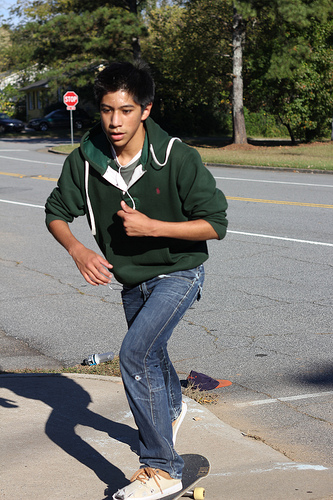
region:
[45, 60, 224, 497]
boy on skateboard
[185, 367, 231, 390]
blue and orange baseball cap on ground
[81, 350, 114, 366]
empty plastic bottle in the street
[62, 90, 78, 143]
stop sign in distance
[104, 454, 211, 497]
skateboard with white wheels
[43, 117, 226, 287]
green hoodie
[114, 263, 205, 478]
blue jeans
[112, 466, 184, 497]
tan shoe with a hole in the toe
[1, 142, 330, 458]
street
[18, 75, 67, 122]
house in background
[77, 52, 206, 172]
He is not an adult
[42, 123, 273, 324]
His jacket is dark green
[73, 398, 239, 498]
The skateboard is black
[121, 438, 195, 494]
His laces are orange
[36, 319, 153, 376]
Trash on the ground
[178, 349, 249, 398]
Someone's hat is not on their head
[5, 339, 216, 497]
A shadow is on the sidewalk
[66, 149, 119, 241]
The laces are white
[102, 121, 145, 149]
His mouth is open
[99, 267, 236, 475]
His jeans are dark blue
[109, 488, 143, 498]
hole in left sneaker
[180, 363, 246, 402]
orange and blue baseball hat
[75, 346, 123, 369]
empty plastic drink bottle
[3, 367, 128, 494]
black shadow of skateboarder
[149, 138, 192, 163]
White string on skateboarder's hoodie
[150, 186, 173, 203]
red logo on green hoodie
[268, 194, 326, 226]
yellow line in the middle of road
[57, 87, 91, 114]
red stop sign at corner of road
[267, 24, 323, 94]
greenery in upper right portion of picture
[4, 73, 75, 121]
yellow house with brown shutters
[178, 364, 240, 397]
orange and blue baseball cap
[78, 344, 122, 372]
empty plastic water bottle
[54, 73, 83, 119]
red octagon stop sign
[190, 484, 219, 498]
Back left yellow skateboard wheel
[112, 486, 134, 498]
Hole in top of yellow sneaker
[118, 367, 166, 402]
hole in knee area of blue jeans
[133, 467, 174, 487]
orange shoe laces on yellow shoes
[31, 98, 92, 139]
dark car located on right in driveway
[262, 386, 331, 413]
white lines painted on pavement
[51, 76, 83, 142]
The stop sign is red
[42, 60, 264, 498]
The boy is skateboarding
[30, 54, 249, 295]
The boy is wearing a green sweater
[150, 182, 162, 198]
Red emblem on the jacket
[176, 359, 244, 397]
A hat in the street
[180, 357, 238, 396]
The hat is blue and orange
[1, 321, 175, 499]
Boy's shadow on the sidewalk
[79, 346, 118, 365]
Empty bottle in the street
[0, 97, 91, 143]
Both cars are parked